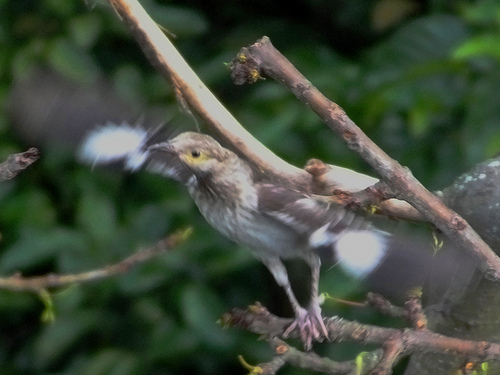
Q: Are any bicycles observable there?
A: No, there are no bicycles.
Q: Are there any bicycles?
A: No, there are no bicycles.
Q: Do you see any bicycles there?
A: No, there are no bicycles.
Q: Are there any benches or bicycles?
A: No, there are no bicycles or benches.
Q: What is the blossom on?
A: The blossom is on the branch.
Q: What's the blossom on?
A: The blossom is on the branch.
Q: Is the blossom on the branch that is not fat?
A: Yes, the blossom is on the branch.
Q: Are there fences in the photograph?
A: No, there are no fences.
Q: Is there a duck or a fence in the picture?
A: No, there are no fences or ducks.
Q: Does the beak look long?
A: Yes, the beak is long.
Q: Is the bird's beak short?
A: No, the beak is long.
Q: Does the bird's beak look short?
A: No, the beak is long.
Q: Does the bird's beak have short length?
A: No, the beak is long.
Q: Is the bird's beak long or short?
A: The beak is long.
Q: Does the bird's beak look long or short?
A: The beak is long.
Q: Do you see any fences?
A: No, there are no fences.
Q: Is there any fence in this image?
A: No, there are no fences.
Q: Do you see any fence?
A: No, there are no fences.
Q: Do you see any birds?
A: Yes, there is a bird.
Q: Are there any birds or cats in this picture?
A: Yes, there is a bird.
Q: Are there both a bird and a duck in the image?
A: No, there is a bird but no ducks.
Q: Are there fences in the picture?
A: No, there are no fences.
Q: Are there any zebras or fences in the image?
A: No, there are no fences or zebras.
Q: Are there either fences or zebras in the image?
A: No, there are no fences or zebras.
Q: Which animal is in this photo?
A: The animal is a bird.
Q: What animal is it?
A: The animal is a bird.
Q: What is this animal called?
A: This is a bird.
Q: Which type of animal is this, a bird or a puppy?
A: This is a bird.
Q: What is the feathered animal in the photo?
A: The animal is a bird.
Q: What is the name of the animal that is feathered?
A: The animal is a bird.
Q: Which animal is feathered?
A: The animal is a bird.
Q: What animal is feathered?
A: The animal is a bird.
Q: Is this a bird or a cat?
A: This is a bird.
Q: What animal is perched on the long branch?
A: The bird is perched on the branch.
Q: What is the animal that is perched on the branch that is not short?
A: The animal is a bird.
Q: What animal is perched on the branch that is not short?
A: The animal is a bird.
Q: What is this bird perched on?
A: The bird is perched on the branch.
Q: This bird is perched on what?
A: The bird is perched on the branch.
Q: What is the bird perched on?
A: The bird is perched on the branch.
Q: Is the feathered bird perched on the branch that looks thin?
A: Yes, the bird is perched on the branch.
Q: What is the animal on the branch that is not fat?
A: The animal is a bird.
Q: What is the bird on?
A: The bird is on the branch.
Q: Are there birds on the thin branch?
A: Yes, there is a bird on the branch.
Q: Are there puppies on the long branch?
A: No, there is a bird on the branch.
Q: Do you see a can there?
A: No, there are no cans.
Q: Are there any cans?
A: No, there are no cans.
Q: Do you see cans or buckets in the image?
A: No, there are no cans or buckets.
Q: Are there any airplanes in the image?
A: No, there are no airplanes.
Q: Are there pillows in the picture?
A: No, there are no pillows.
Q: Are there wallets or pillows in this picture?
A: No, there are no pillows or wallets.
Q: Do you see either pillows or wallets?
A: No, there are no pillows or wallets.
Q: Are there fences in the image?
A: No, there are no fences.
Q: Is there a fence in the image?
A: No, there are no fences.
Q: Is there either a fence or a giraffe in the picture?
A: No, there are no fences or giraffes.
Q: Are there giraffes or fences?
A: No, there are no fences or giraffes.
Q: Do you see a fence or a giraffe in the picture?
A: No, there are no fences or giraffes.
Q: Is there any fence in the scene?
A: No, there are no fences.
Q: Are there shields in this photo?
A: No, there are no shields.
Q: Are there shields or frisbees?
A: No, there are no shields or frisbees.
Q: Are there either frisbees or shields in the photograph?
A: No, there are no shields or frisbees.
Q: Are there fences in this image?
A: No, there are no fences.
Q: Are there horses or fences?
A: No, there are no fences or horses.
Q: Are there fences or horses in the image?
A: No, there are no fences or horses.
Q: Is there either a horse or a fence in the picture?
A: No, there are no fences or horses.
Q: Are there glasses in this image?
A: No, there are no glasses.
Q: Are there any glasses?
A: No, there are no glasses.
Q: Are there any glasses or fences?
A: No, there are no glasses or fences.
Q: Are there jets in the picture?
A: No, there are no jets.